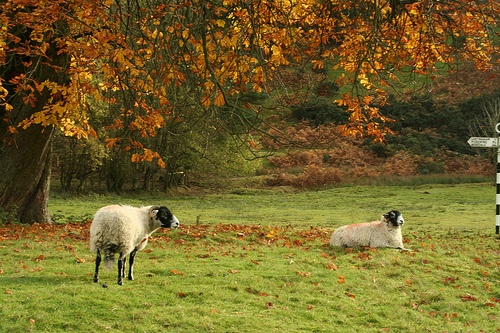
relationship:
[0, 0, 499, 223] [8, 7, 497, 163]
tree has leaves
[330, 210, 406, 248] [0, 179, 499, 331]
sheep lying on ground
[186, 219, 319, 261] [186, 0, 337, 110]
fallen leaves under branches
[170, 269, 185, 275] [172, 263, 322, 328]
fallen leaves fallen on ground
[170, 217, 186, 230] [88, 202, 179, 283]
nose of ram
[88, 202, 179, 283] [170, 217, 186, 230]
ram has nose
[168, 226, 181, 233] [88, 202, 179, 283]
mouth of ram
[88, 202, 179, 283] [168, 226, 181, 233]
ram has mouth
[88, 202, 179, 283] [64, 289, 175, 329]
ram on grass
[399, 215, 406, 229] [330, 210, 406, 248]
nose of sheep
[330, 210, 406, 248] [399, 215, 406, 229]
sheep has nose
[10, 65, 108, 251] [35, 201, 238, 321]
trunk on grass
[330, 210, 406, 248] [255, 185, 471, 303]
sheep on grass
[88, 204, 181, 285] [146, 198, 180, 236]
ram has head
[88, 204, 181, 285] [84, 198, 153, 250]
ram has body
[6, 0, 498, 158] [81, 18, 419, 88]
branches has autumn leaves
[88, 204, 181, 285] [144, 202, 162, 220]
ram has horns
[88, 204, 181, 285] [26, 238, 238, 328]
ram on grass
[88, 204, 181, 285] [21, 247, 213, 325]
ram on grass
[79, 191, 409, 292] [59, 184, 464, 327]
sheep on grass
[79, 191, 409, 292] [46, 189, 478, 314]
sheep on grass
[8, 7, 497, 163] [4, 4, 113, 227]
leaves on tree